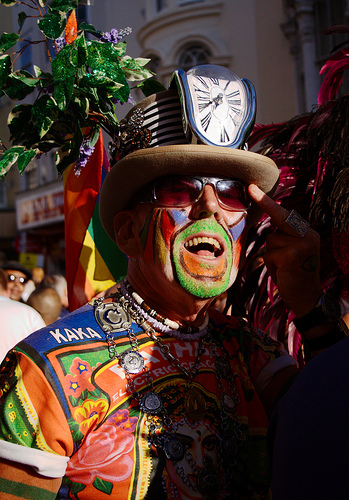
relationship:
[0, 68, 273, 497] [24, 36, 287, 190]
man wearing top hat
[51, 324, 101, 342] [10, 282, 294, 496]
letters on shirt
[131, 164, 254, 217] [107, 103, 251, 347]
glasses worn by man